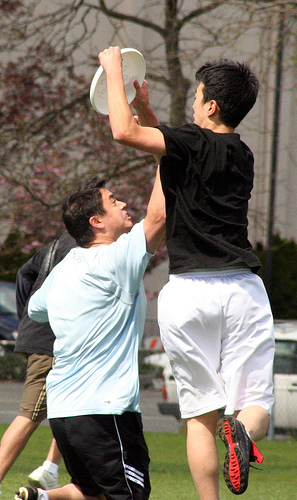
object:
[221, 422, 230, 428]
nub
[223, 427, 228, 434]
nub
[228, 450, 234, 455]
nub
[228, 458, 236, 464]
nub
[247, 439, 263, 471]
cleat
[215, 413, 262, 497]
shoe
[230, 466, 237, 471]
bump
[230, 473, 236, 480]
bump